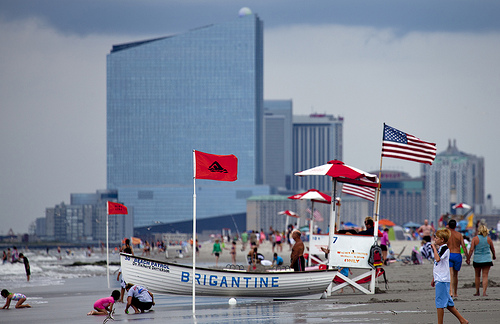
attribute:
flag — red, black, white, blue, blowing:
[192, 148, 238, 317]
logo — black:
[206, 160, 229, 174]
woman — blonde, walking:
[465, 221, 496, 294]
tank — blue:
[472, 233, 493, 264]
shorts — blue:
[448, 253, 462, 270]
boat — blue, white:
[119, 250, 338, 300]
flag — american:
[374, 121, 438, 247]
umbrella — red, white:
[293, 159, 377, 295]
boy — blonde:
[430, 229, 470, 324]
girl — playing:
[1, 289, 32, 309]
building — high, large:
[105, 6, 265, 231]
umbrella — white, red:
[288, 188, 332, 265]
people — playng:
[0, 239, 120, 282]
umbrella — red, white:
[277, 209, 300, 243]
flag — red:
[105, 197, 129, 287]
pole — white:
[191, 150, 197, 324]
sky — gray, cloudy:
[3, 3, 499, 236]